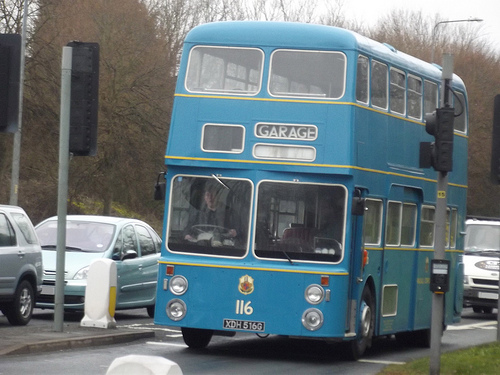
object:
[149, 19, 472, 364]
bus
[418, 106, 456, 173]
signal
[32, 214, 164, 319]
car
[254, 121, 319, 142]
license